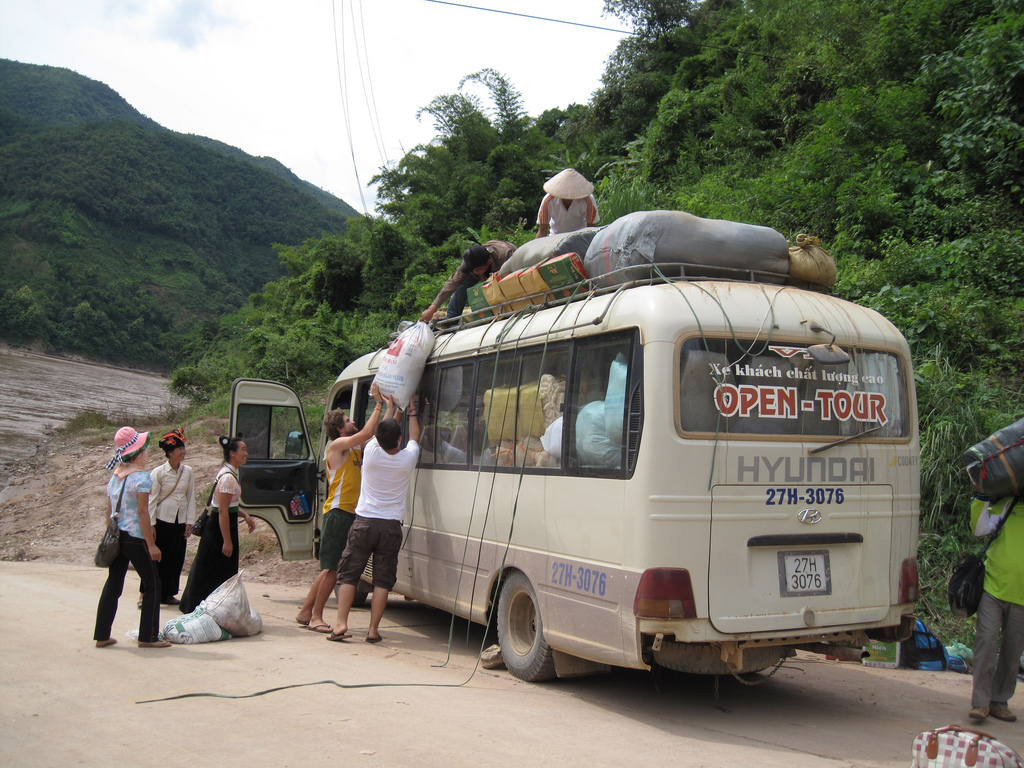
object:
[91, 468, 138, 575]
purse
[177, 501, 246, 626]
skirt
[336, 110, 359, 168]
line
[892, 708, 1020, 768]
bag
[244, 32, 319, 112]
cloud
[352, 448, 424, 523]
shirt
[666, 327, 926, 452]
window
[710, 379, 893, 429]
writing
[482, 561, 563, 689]
tire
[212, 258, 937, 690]
bus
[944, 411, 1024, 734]
person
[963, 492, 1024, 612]
shirt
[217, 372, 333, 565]
door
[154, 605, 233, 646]
bag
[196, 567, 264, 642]
bag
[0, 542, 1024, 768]
ground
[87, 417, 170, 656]
person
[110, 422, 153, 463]
hat